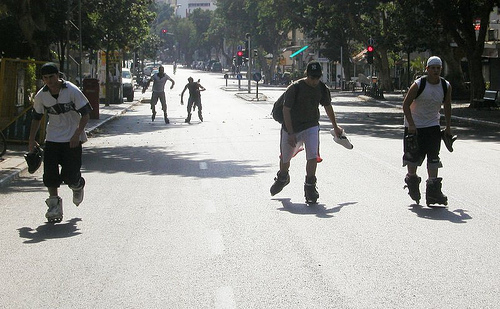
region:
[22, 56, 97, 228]
a guy skating down the street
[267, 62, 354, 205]
a guy in a black shirt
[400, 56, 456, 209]
a guy in a white hat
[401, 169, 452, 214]
rollerblades on a man's feet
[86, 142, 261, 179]
the shadow of a tree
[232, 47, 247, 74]
a red traffic light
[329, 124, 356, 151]
shoes that a man is holding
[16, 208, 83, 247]
a guy's shadow on the ground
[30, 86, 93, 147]
a shirt the guy is wearing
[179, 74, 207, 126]
a guy trying to catch up with the others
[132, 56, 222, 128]
TWO PEOPLE ROLLERBLADING IN THE BACKGROUND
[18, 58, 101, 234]
MAN WEARING A BLACK HAT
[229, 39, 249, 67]
A RED TRAFFIC SIGNAL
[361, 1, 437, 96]
A TREE NEXT TO A TRAFFIC LIGHT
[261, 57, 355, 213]
A MAN ROLLERBLADING WITH A BACKPACK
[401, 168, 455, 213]
A PAIR OF BLACK ROLLARBLADES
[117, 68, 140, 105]
A TRUCK IN THE BACKGROUND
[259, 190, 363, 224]
A SHADOW ON THE GROUND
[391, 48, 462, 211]
MAN WEARING A WHITE TEE SHIRT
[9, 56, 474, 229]
THREE PEOPLE ROLLERBLADING DOWN THE STREET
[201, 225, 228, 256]
White line on street.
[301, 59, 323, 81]
Hat on person's head.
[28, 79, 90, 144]
Short sleeved white shirt.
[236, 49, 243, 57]
Red light in background.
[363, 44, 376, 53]
Red light in background.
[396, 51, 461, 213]
man using inline skates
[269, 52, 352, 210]
man in black hat skating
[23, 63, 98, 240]
man skating up the road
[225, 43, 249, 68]
red light in middle of the road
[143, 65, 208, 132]
two men skating up the road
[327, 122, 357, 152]
man carrying tennis shoes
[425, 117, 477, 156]
man holding his shoes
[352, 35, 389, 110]
red light on the side of the road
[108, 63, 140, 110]
white vehicle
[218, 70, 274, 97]
road signs in the middle of the road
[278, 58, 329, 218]
a man roller blading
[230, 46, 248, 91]
a red stop light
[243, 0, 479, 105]
many large trees in the background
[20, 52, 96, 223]
a man roller blading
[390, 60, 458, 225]
a man roller blading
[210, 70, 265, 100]
three blue street signs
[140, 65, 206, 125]
two men roller blading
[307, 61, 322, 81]
a yankees hat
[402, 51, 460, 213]
a man in a white tee shirt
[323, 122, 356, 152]
sneakers being carried by roller blader